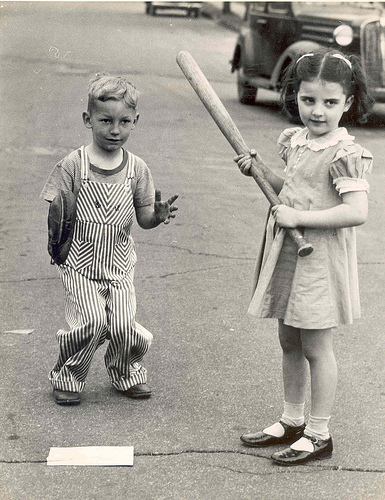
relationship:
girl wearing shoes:
[237, 47, 371, 476] [235, 412, 349, 466]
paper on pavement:
[41, 434, 145, 476] [3, 414, 203, 498]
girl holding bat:
[237, 47, 371, 476] [170, 45, 317, 260]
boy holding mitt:
[39, 69, 184, 407] [37, 188, 90, 272]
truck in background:
[227, 3, 384, 130] [2, 3, 385, 135]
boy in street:
[39, 69, 184, 407] [2, 3, 385, 496]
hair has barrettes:
[267, 47, 375, 134] [292, 48, 357, 73]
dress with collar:
[247, 121, 373, 335] [285, 121, 360, 159]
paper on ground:
[41, 434, 145, 476] [2, 419, 385, 496]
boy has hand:
[39, 69, 184, 407] [142, 184, 183, 231]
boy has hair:
[39, 69, 184, 407] [78, 69, 144, 120]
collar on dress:
[285, 121, 360, 159] [247, 121, 373, 335]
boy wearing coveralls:
[39, 69, 184, 407] [43, 148, 170, 399]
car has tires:
[227, 3, 384, 130] [225, 44, 264, 111]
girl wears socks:
[237, 47, 371, 476] [252, 398, 341, 456]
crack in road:
[1, 429, 385, 487] [2, 3, 385, 496]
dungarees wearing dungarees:
[39, 69, 184, 407] [43, 148, 170, 399]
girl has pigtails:
[237, 47, 371, 476] [277, 47, 376, 129]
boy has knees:
[39, 69, 184, 407] [63, 303, 158, 348]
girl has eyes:
[237, 47, 371, 476] [299, 90, 346, 111]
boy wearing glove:
[39, 69, 184, 407] [37, 188, 90, 272]